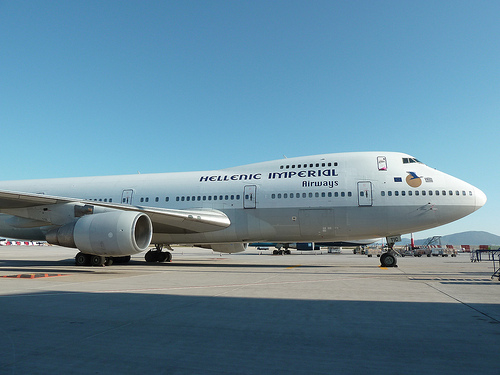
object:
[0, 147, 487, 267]
plane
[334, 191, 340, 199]
window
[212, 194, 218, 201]
window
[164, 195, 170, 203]
window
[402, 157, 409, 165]
window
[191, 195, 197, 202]
window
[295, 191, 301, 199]
window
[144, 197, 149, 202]
window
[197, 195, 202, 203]
window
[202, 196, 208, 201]
window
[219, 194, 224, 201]
window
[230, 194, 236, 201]
window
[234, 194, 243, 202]
window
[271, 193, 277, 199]
window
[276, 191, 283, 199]
window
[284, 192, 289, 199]
window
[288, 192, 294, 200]
window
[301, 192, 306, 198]
window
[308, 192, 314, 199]
window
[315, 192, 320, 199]
window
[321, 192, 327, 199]
window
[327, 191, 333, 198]
window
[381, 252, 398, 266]
wheel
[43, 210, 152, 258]
engine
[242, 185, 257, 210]
door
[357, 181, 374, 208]
door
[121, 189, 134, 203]
door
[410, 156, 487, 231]
tip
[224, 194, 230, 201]
window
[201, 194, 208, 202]
window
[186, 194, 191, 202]
window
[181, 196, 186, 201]
window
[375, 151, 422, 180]
cock-pit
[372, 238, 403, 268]
landing-gear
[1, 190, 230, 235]
right wing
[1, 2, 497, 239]
sky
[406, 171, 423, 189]
emblem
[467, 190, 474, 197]
windows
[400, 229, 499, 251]
hillside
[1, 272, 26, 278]
orange paint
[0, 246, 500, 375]
ground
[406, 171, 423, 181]
blue-bird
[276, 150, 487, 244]
front